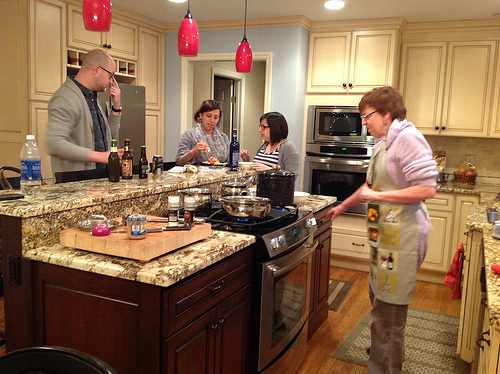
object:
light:
[177, 12, 200, 58]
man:
[46, 49, 123, 183]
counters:
[0, 163, 281, 219]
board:
[57, 214, 214, 263]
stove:
[302, 156, 378, 218]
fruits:
[456, 167, 467, 175]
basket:
[451, 172, 478, 185]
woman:
[329, 87, 437, 373]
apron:
[365, 141, 420, 308]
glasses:
[100, 63, 116, 80]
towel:
[445, 243, 466, 300]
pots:
[218, 193, 273, 218]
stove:
[164, 197, 318, 373]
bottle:
[19, 132, 41, 200]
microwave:
[307, 104, 382, 158]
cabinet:
[305, 25, 401, 95]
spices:
[183, 194, 198, 225]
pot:
[258, 168, 299, 206]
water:
[22, 181, 42, 199]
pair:
[166, 194, 197, 225]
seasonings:
[165, 193, 183, 231]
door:
[305, 31, 349, 93]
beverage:
[140, 144, 150, 180]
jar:
[126, 213, 147, 240]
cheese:
[127, 226, 147, 240]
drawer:
[162, 250, 254, 339]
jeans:
[368, 282, 410, 373]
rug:
[332, 297, 474, 373]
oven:
[253, 209, 319, 373]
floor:
[299, 261, 473, 373]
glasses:
[360, 108, 380, 122]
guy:
[46, 47, 123, 182]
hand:
[109, 76, 122, 106]